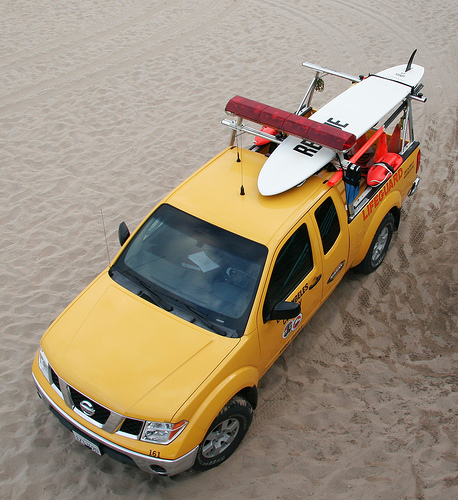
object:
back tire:
[351, 211, 395, 275]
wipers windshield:
[123, 217, 260, 319]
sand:
[1, 3, 458, 498]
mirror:
[118, 221, 131, 247]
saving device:
[367, 151, 405, 188]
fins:
[345, 182, 360, 204]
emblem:
[282, 319, 295, 338]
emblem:
[292, 312, 303, 331]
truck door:
[256, 211, 325, 368]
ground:
[60, 91, 138, 134]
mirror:
[271, 300, 302, 321]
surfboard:
[256, 48, 424, 197]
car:
[29, 60, 427, 482]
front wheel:
[193, 393, 253, 474]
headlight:
[36, 348, 49, 382]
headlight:
[140, 418, 189, 446]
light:
[224, 92, 358, 168]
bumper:
[28, 370, 199, 479]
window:
[313, 195, 340, 255]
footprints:
[1, 460, 24, 500]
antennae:
[100, 208, 113, 277]